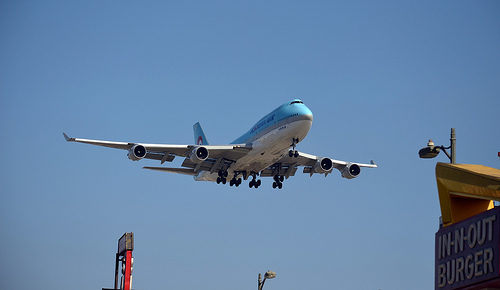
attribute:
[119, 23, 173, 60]
sky — blue, clear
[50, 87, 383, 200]
plane — blue, silver, large, white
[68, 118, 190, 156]
wing — big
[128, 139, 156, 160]
engine — white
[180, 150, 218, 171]
engine — white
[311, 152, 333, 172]
engine — white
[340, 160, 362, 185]
engine — white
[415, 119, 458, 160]
light — gray, bright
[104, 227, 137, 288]
isgn — orange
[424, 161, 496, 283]
sign — large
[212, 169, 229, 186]
wheel — black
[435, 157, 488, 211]
arrow — yellow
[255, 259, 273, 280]
light — gray